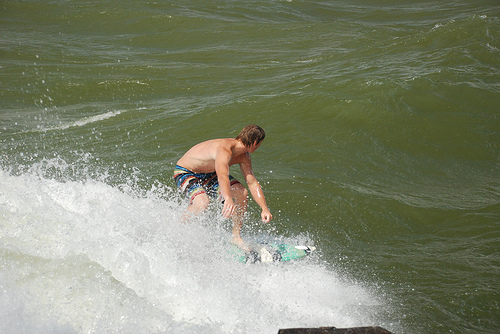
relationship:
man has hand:
[147, 77, 324, 325] [258, 210, 273, 225]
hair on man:
[235, 124, 265, 149] [147, 77, 324, 325]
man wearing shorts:
[147, 77, 324, 325] [174, 161, 241, 206]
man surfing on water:
[147, 77, 324, 325] [293, 114, 421, 229]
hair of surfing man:
[235, 124, 265, 149] [169, 109, 278, 245]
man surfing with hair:
[147, 77, 324, 325] [236, 123, 273, 148]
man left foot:
[147, 77, 324, 325] [227, 231, 247, 243]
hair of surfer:
[235, 124, 265, 149] [170, 124, 271, 256]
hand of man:
[258, 210, 273, 225] [142, 110, 300, 282]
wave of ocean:
[2, 147, 411, 329] [189, 27, 399, 86]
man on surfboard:
[147, 77, 324, 325] [213, 242, 318, 262]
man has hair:
[147, 77, 324, 325] [233, 123, 265, 144]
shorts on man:
[167, 168, 240, 206] [167, 123, 277, 257]